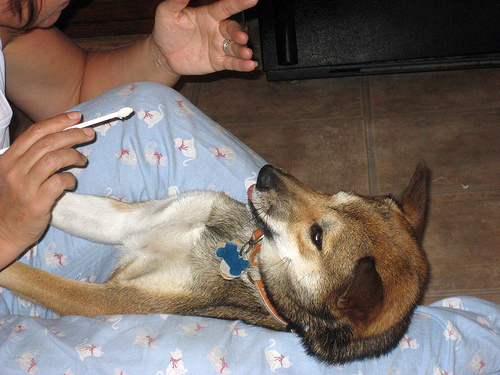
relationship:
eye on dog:
[308, 223, 324, 253] [1, 159, 431, 366]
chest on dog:
[113, 188, 236, 295] [1, 159, 431, 366]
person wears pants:
[1, 0, 498, 374] [1, 83, 498, 372]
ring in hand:
[222, 39, 232, 57] [149, 0, 299, 80]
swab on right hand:
[0, 105, 134, 155] [0, 110, 97, 248]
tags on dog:
[214, 236, 251, 278] [6, 144, 441, 369]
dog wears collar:
[1, 159, 431, 366] [215, 228, 298, 333]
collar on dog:
[247, 223, 295, 327] [1, 159, 431, 366]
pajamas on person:
[0, 80, 494, 371] [1, 0, 498, 374]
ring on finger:
[222, 39, 232, 57] [217, 35, 255, 57]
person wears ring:
[1, 0, 498, 374] [222, 39, 232, 57]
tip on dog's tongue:
[236, 179, 257, 206] [191, 152, 437, 314]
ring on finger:
[211, 31, 248, 63] [220, 33, 255, 60]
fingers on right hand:
[8, 103, 98, 196] [0, 110, 97, 248]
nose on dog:
[251, 155, 288, 194] [0, 153, 444, 353]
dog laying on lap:
[1, 159, 431, 366] [31, 80, 496, 373]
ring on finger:
[222, 39, 232, 57] [209, 39, 254, 56]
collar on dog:
[215, 228, 298, 333] [0, 156, 430, 369]